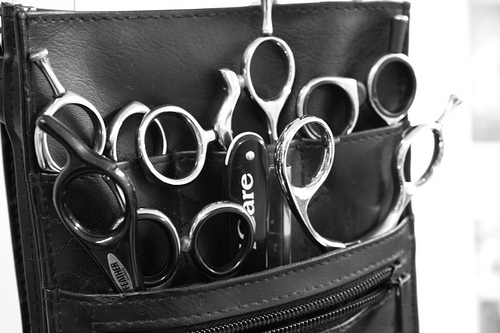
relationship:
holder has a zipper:
[1, 1, 420, 333] [155, 258, 411, 333]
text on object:
[238, 173, 257, 252] [226, 133, 268, 277]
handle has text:
[91, 236, 144, 294] [109, 261, 130, 292]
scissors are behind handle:
[135, 1, 295, 188] [91, 236, 144, 294]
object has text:
[226, 133, 268, 277] [238, 173, 257, 252]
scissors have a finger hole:
[297, 14, 419, 138] [376, 61, 416, 113]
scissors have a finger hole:
[135, 1, 295, 188] [251, 41, 290, 99]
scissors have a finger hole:
[273, 94, 463, 253] [287, 121, 332, 188]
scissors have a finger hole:
[39, 115, 141, 295] [63, 170, 128, 236]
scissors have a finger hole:
[135, 1, 295, 188] [145, 111, 201, 179]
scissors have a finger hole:
[273, 94, 463, 253] [403, 128, 436, 183]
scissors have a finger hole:
[29, 48, 168, 173] [48, 104, 105, 169]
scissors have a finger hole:
[29, 48, 168, 173] [118, 114, 164, 163]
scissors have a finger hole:
[102, 173, 256, 293] [198, 213, 251, 273]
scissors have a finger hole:
[102, 173, 256, 293] [136, 219, 175, 280]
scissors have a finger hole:
[297, 14, 419, 138] [305, 79, 353, 137]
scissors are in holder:
[297, 14, 419, 138] [1, 1, 420, 333]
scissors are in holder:
[273, 94, 463, 253] [1, 1, 420, 333]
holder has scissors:
[1, 1, 420, 333] [102, 173, 256, 293]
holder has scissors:
[1, 1, 420, 333] [29, 48, 168, 173]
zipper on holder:
[155, 258, 411, 333] [1, 1, 420, 333]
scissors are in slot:
[273, 94, 463, 253] [55, 211, 409, 295]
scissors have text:
[39, 115, 141, 295] [109, 261, 130, 292]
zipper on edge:
[155, 258, 411, 333] [23, 214, 414, 332]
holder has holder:
[1, 1, 420, 333] [0, 1, 420, 333]